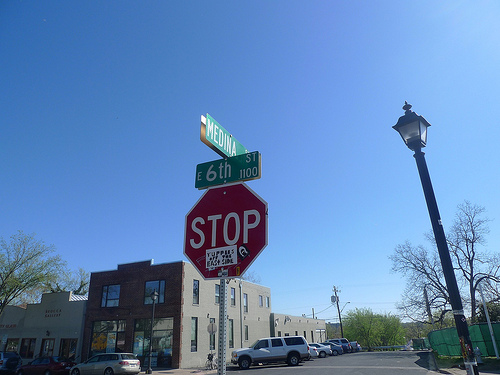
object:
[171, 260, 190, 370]
edge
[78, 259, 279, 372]
building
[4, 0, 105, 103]
sky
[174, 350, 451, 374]
road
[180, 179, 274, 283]
sign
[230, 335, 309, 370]
truck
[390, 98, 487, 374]
light pole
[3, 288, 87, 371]
store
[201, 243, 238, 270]
sticker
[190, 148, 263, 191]
sign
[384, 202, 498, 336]
tree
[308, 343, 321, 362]
vehicle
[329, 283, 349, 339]
post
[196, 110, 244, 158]
sign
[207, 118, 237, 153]
medina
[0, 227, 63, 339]
tree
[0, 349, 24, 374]
suv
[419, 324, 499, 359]
fence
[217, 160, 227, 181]
letter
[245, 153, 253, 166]
letter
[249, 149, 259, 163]
letter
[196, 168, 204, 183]
letter